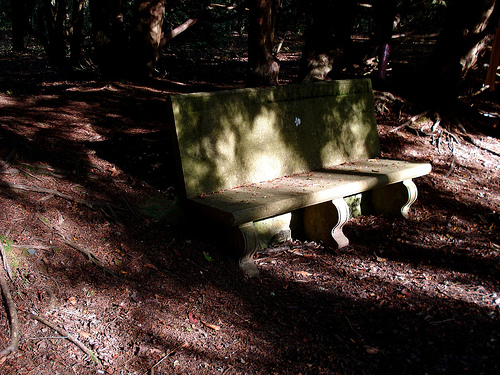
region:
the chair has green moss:
[177, 90, 392, 150]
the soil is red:
[80, 229, 381, 363]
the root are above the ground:
[21, 173, 134, 359]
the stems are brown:
[139, 5, 309, 65]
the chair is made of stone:
[176, 100, 418, 234]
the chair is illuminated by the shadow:
[176, 96, 448, 232]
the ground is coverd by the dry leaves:
[107, 283, 438, 371]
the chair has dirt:
[211, 155, 426, 191]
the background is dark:
[13, 13, 103, 70]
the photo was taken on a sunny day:
[23, 6, 480, 356]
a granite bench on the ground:
[163, 74, 432, 268]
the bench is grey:
[167, 77, 432, 272]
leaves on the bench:
[190, 139, 420, 203]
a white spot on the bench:
[291, 116, 305, 129]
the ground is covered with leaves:
[12, 74, 497, 374]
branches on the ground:
[5, 165, 195, 367]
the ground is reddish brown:
[2, 64, 481, 374]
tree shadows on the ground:
[4, 54, 489, 373]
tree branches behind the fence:
[3, 2, 495, 101]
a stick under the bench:
[264, 240, 316, 259]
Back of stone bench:
[157, 75, 392, 195]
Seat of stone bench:
[177, 150, 445, 226]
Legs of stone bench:
[204, 180, 422, 281]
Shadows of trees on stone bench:
[163, 77, 385, 201]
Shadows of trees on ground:
[100, 167, 498, 362]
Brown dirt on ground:
[24, 92, 497, 363]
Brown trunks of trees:
[90, 5, 497, 94]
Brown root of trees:
[0, 228, 35, 363]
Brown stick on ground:
[24, 293, 121, 373]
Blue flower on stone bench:
[282, 109, 307, 131]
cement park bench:
[168, 75, 436, 279]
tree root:
[2, 277, 27, 367]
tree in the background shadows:
[117, 3, 196, 86]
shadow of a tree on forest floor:
[261, 282, 498, 374]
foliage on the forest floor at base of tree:
[1, 233, 65, 300]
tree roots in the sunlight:
[385, 105, 497, 164]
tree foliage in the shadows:
[2, 2, 101, 72]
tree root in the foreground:
[24, 302, 101, 373]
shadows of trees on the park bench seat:
[170, 91, 377, 155]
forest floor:
[126, 287, 244, 374]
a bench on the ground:
[168, 82, 430, 238]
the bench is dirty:
[159, 74, 436, 278]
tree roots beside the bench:
[378, 67, 497, 192]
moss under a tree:
[2, 240, 17, 312]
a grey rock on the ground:
[23, 241, 42, 259]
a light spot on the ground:
[385, 87, 497, 207]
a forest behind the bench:
[1, 5, 496, 130]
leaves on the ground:
[175, 307, 225, 336]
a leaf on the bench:
[369, 164, 384, 178]